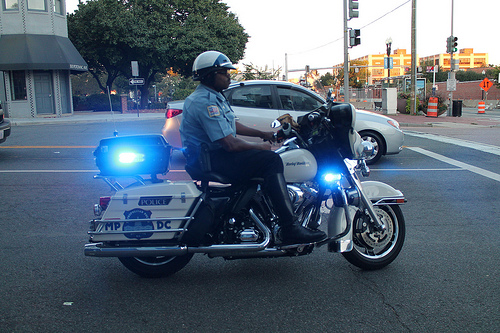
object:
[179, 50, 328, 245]
cop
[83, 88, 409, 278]
motorcycle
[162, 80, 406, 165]
car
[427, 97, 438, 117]
barrel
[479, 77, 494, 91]
sign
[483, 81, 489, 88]
arrows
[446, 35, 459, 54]
trafficlight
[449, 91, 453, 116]
pole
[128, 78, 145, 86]
one way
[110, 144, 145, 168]
blue light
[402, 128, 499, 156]
line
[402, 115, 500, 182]
crosswalk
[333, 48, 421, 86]
building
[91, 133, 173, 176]
trunk case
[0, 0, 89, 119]
apartment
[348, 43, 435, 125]
corner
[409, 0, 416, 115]
pole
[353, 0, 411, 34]
power line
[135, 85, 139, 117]
post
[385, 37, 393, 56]
streetlight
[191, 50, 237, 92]
helmet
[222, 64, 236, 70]
visor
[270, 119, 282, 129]
side mirror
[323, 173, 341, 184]
blue light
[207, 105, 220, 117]
badge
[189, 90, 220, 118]
shoulder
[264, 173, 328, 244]
boot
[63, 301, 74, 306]
white spot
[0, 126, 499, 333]
street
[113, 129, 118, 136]
knob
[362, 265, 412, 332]
crack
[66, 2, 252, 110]
trees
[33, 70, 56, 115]
door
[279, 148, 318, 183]
gas tank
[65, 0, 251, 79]
leaves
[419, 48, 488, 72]
large building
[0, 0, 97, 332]
left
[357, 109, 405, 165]
front